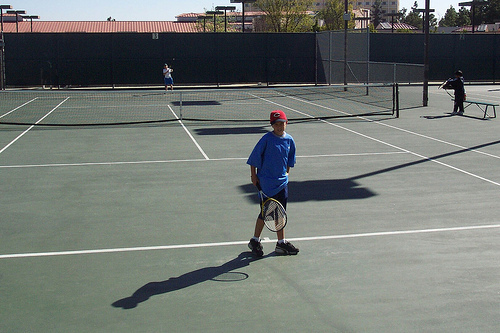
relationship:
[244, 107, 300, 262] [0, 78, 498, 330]
boy on tennis court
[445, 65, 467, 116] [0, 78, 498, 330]
boy on tennis court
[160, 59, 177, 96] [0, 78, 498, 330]
boy on tennis court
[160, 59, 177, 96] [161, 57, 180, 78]
boy playing tennis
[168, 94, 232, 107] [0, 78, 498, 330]
shadow on tennis court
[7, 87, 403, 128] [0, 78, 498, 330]
net in center of tennis court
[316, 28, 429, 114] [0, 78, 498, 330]
fence surrounds tennis court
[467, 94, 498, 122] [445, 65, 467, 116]
bench for boy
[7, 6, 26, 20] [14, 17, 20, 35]
lighting on post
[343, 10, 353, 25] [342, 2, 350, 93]
sign on post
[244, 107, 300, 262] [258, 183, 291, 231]
boy holding tennis racket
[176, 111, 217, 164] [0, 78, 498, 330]
white line on tennis court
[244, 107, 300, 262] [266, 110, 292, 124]
boy has hat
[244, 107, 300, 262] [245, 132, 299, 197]
boy has shirt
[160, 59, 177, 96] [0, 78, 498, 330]
boy in back of tennis court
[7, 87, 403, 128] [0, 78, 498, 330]
net at center of tennis court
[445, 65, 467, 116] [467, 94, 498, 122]
boy near bench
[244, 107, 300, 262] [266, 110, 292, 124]
boy wearing hat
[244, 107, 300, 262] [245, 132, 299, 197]
boy wearing shirt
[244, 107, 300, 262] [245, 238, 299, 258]
boy wearing shoes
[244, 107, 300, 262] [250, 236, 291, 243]
boy wearing socks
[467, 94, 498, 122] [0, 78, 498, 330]
bench on tennis court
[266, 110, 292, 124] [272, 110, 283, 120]
hat for cardinal baseball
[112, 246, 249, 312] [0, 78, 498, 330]
shadow on tennis court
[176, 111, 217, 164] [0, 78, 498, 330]
white line going across tennis court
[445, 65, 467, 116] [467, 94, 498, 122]
boy next to bench